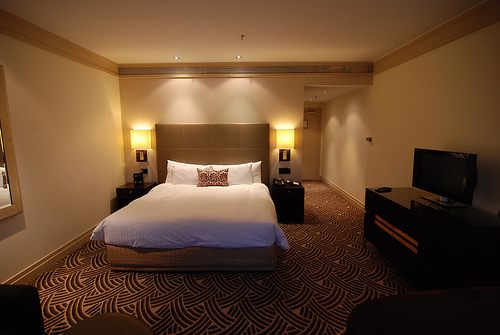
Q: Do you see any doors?
A: Yes, there is a door.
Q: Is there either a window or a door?
A: Yes, there is a door.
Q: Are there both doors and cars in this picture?
A: No, there is a door but no cars.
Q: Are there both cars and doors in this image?
A: No, there is a door but no cars.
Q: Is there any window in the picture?
A: No, there are no windows.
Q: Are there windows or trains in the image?
A: No, there are no windows or trains.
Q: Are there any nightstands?
A: Yes, there is a nightstand.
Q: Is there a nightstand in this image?
A: Yes, there is a nightstand.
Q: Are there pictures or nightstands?
A: Yes, there is a nightstand.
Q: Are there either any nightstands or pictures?
A: Yes, there is a nightstand.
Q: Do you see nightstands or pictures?
A: Yes, there is a nightstand.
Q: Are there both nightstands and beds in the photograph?
A: Yes, there are both a nightstand and a bed.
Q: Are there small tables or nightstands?
A: Yes, there is a small nightstand.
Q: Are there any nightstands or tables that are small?
A: Yes, the nightstand is small.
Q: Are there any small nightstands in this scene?
A: Yes, there is a small nightstand.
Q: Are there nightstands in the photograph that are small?
A: Yes, there is a nightstand that is small.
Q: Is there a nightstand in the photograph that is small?
A: Yes, there is a nightstand that is small.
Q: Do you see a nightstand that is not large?
A: Yes, there is a small nightstand.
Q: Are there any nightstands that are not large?
A: Yes, there is a small nightstand.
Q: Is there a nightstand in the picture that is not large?
A: Yes, there is a small nightstand.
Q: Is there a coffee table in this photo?
A: No, there are no coffee tables.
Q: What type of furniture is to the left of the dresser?
A: The piece of furniture is a nightstand.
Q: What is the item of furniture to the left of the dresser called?
A: The piece of furniture is a nightstand.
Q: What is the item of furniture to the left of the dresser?
A: The piece of furniture is a nightstand.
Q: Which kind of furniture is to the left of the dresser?
A: The piece of furniture is a nightstand.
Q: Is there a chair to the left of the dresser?
A: No, there is a nightstand to the left of the dresser.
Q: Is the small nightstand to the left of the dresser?
A: Yes, the nightstand is to the left of the dresser.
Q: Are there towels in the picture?
A: No, there are no towels.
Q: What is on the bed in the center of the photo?
A: The quilt is on the bed.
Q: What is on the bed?
A: The quilt is on the bed.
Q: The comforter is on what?
A: The comforter is on the bed.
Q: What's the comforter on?
A: The comforter is on the bed.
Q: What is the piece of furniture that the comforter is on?
A: The piece of furniture is a bed.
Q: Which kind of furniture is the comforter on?
A: The comforter is on the bed.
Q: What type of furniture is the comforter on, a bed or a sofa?
A: The comforter is on a bed.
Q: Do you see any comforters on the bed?
A: Yes, there is a comforter on the bed.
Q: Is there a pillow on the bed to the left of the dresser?
A: No, there is a comforter on the bed.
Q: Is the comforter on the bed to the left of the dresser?
A: Yes, the comforter is on the bed.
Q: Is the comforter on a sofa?
A: No, the comforter is on the bed.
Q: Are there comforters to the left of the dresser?
A: Yes, there is a comforter to the left of the dresser.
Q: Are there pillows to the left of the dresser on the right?
A: No, there is a comforter to the left of the dresser.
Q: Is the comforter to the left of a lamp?
A: No, the comforter is to the left of the dresser.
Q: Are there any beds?
A: Yes, there is a bed.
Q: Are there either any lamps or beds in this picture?
A: Yes, there is a bed.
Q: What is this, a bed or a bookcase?
A: This is a bed.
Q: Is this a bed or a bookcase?
A: This is a bed.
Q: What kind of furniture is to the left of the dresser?
A: The piece of furniture is a bed.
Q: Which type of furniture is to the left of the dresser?
A: The piece of furniture is a bed.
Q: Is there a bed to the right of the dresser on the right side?
A: No, the bed is to the left of the dresser.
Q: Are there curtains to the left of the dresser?
A: No, there is a bed to the left of the dresser.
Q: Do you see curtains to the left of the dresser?
A: No, there is a bed to the left of the dresser.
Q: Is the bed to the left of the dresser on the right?
A: Yes, the bed is to the left of the dresser.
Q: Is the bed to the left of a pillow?
A: No, the bed is to the left of the dresser.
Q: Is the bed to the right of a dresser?
A: No, the bed is to the left of a dresser.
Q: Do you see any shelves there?
A: No, there are no shelves.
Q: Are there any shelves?
A: No, there are no shelves.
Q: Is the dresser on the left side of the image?
A: No, the dresser is on the right of the image.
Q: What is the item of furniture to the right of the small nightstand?
A: The piece of furniture is a dresser.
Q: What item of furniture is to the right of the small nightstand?
A: The piece of furniture is a dresser.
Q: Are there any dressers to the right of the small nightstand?
A: Yes, there is a dresser to the right of the nightstand.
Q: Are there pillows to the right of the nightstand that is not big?
A: No, there is a dresser to the right of the nightstand.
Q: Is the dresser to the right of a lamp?
A: No, the dresser is to the right of the nightstand.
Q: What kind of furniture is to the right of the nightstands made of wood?
A: The piece of furniture is a dresser.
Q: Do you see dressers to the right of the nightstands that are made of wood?
A: Yes, there is a dresser to the right of the nightstands.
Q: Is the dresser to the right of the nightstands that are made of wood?
A: Yes, the dresser is to the right of the nightstands.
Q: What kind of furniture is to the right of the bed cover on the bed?
A: The piece of furniture is a dresser.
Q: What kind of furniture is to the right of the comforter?
A: The piece of furniture is a dresser.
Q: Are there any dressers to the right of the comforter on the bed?
A: Yes, there is a dresser to the right of the quilt.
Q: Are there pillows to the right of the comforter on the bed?
A: No, there is a dresser to the right of the comforter.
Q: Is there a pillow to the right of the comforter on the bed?
A: No, there is a dresser to the right of the comforter.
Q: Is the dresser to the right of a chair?
A: No, the dresser is to the right of the comforter.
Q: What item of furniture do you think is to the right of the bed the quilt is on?
A: The piece of furniture is a dresser.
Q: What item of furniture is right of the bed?
A: The piece of furniture is a dresser.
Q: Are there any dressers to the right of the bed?
A: Yes, there is a dresser to the right of the bed.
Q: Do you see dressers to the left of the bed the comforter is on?
A: No, the dresser is to the right of the bed.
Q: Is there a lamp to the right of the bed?
A: No, there is a dresser to the right of the bed.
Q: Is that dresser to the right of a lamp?
A: No, the dresser is to the right of the bed.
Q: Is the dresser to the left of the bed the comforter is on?
A: No, the dresser is to the right of the bed.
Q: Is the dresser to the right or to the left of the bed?
A: The dresser is to the right of the bed.